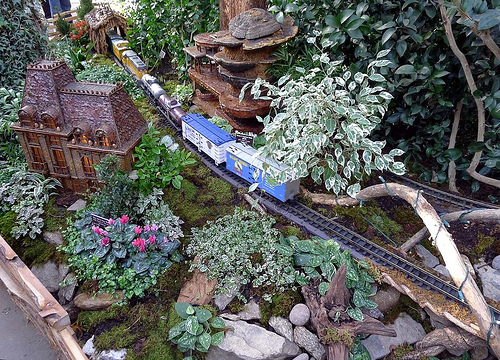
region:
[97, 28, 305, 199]
A train.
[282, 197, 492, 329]
The train track is black.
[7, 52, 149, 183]
A building.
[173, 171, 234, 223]
Moss is growing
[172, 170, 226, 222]
The moss is green.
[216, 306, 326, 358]
Rocks are in the picture.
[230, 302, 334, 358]
The rocks are gray.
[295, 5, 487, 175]
Plants are in the background.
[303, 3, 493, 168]
The plants are green.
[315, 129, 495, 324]
The wood is brown and gray.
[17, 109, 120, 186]
The windows of the brown house.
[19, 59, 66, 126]
The taller roof of the brown house.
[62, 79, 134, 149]
The lower roof of the brown house.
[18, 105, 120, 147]
The windows closest to the roofs of the brown house.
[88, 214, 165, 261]
The purple flowers near the brown house.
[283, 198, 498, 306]
The tracks in front of the train.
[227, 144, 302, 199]
The blue train car.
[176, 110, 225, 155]
The white train car.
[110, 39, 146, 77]
The two yellow train cars.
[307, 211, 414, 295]
rail road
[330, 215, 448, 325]
rail road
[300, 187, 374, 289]
rail road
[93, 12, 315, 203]
A long toy train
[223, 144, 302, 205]
Last car is blue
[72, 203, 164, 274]
Pretty pink flowers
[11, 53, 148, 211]
A brown building beside tracks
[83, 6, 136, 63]
A brown tunnel for train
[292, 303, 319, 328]
A round gray rock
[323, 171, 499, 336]
String of lights around branch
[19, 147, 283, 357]
Moss growing on rocks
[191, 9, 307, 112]
Fungus growing out of tree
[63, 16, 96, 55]
Orange flowers by tunnel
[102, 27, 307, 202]
a train passing along the track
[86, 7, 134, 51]
an old looking shed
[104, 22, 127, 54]
tunnel passage in the shed for the train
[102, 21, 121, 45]
train car passing through a small structure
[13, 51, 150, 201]
a brown house standing near the track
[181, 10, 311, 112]
fungus growing on a tree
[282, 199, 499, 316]
portion of train track not being used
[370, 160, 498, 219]
second set of train tracks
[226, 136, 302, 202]
last car of the train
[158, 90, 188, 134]
maroon tanker car